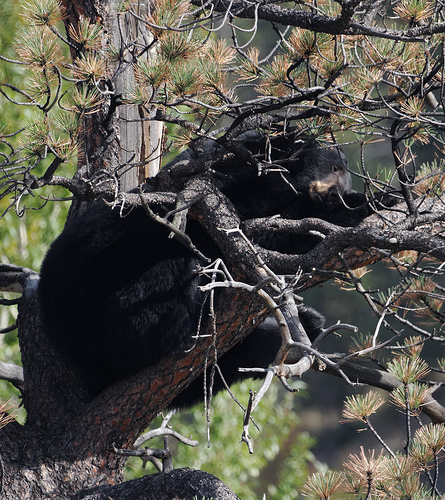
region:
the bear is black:
[46, 124, 429, 404]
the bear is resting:
[53, 152, 367, 400]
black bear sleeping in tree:
[39, 120, 416, 413]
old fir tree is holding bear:
[0, 0, 443, 499]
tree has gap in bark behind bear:
[107, 0, 168, 195]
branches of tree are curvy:
[0, 0, 444, 499]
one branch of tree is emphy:
[138, 185, 443, 453]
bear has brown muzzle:
[308, 169, 351, 206]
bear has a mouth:
[312, 183, 325, 201]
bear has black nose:
[327, 187, 340, 201]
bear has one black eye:
[331, 166, 337, 174]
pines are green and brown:
[0, 0, 443, 499]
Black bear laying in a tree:
[15, 106, 411, 350]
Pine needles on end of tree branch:
[333, 387, 385, 431]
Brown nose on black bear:
[307, 170, 344, 199]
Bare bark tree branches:
[200, 256, 322, 445]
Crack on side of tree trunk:
[129, 54, 153, 184]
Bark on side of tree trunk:
[36, 403, 133, 478]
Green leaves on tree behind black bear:
[188, 404, 313, 466]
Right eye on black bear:
[329, 159, 340, 175]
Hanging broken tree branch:
[206, 254, 226, 422]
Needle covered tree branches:
[10, 3, 428, 106]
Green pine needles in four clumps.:
[137, 29, 228, 100]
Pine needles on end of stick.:
[343, 389, 405, 451]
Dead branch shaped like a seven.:
[238, 364, 280, 449]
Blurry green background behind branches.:
[119, 375, 333, 493]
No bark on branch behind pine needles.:
[59, 1, 160, 189]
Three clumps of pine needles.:
[342, 354, 441, 423]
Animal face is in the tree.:
[222, 148, 370, 193]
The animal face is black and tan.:
[281, 143, 356, 204]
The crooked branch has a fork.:
[238, 214, 443, 276]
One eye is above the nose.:
[314, 157, 342, 202]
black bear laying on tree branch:
[45, 121, 392, 406]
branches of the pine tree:
[7, 11, 432, 495]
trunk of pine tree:
[14, 53, 175, 489]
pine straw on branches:
[16, 5, 433, 499]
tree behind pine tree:
[5, 56, 323, 489]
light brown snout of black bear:
[312, 169, 352, 202]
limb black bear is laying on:
[133, 184, 443, 418]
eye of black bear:
[329, 162, 339, 174]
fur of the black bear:
[32, 134, 400, 389]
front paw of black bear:
[355, 176, 417, 219]